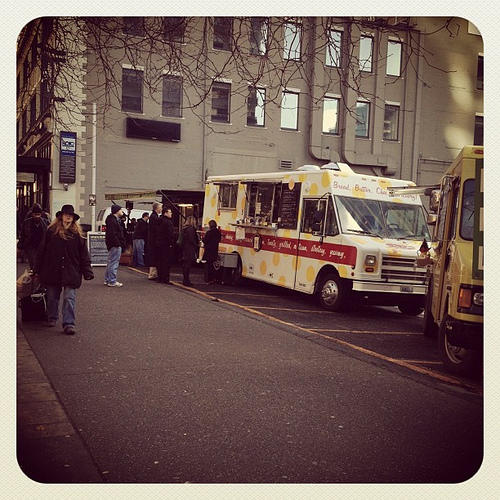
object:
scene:
[14, 19, 483, 483]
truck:
[201, 163, 437, 315]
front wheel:
[317, 273, 351, 310]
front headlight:
[364, 254, 377, 267]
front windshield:
[333, 192, 433, 242]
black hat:
[54, 204, 80, 222]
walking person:
[34, 204, 95, 336]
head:
[61, 204, 75, 224]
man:
[103, 204, 124, 288]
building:
[16, 17, 484, 237]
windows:
[118, 66, 147, 117]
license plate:
[399, 286, 414, 292]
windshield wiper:
[346, 228, 383, 239]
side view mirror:
[313, 211, 324, 225]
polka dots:
[259, 260, 267, 276]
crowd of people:
[104, 201, 221, 287]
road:
[16, 264, 482, 484]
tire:
[398, 305, 425, 316]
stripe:
[221, 229, 357, 266]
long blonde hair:
[47, 213, 84, 240]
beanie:
[111, 205, 122, 215]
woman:
[30, 204, 94, 336]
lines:
[300, 327, 426, 336]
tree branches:
[20, 18, 459, 134]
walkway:
[17, 263, 484, 483]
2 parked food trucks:
[197, 161, 435, 311]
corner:
[40, 16, 69, 226]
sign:
[58, 131, 77, 184]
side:
[195, 170, 362, 312]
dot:
[308, 182, 319, 196]